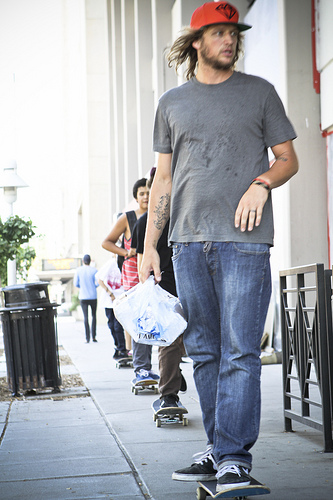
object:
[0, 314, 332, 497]
sidewalk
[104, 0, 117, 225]
line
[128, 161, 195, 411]
man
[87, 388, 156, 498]
crack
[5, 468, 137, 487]
crack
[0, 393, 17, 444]
crack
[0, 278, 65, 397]
trashcan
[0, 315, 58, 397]
side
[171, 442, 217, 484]
tennis shoes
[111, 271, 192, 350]
bag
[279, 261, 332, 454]
gate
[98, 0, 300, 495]
group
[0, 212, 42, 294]
tree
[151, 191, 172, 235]
tattoo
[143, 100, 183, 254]
arm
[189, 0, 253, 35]
hat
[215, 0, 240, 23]
diamond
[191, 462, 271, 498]
skateboard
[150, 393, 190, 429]
skateboard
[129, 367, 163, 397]
skateboard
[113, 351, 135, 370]
skateboard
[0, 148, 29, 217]
street light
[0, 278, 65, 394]
garbage can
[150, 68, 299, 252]
tshirt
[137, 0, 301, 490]
man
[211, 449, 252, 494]
sneakers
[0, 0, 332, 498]
city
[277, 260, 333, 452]
fence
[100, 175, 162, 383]
boy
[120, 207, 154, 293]
shirt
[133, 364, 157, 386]
shoes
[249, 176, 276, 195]
wrist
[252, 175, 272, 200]
bracelet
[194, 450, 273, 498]
vans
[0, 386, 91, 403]
edge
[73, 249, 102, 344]
person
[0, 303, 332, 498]
street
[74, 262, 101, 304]
tshirt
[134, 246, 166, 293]
hand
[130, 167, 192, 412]
person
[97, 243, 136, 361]
person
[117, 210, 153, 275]
backpack